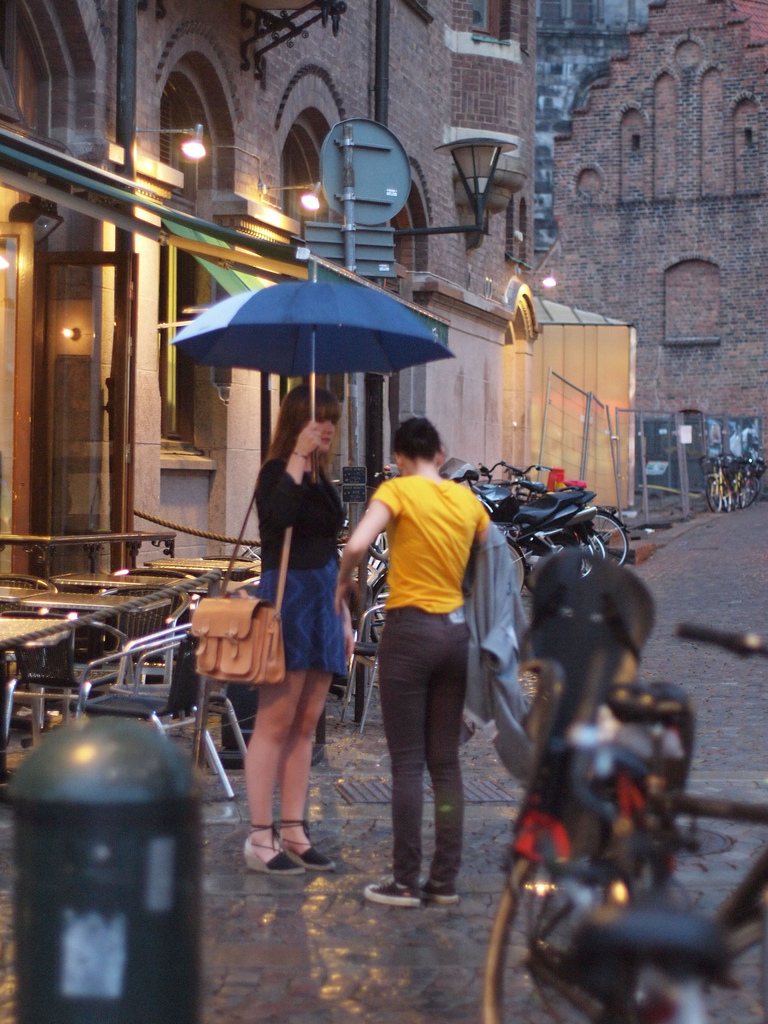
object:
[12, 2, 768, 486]
buildings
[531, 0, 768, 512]
buildings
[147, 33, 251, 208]
archways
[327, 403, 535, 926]
people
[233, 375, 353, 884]
girl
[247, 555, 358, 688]
skirt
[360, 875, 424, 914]
shoe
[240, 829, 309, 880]
shoe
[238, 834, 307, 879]
foot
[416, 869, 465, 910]
shoe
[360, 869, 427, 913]
foot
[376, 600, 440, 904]
leg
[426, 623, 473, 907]
leg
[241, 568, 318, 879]
leg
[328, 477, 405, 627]
arm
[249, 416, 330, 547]
arm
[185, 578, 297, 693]
bag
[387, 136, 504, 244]
pole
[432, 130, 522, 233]
light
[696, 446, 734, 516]
cycles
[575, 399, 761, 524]
fence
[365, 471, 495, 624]
shirt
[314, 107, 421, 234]
sign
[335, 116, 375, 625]
post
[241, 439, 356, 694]
dress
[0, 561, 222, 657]
rope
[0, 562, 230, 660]
bar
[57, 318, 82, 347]
light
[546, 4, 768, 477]
wall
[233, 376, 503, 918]
couple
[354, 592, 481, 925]
pants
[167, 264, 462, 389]
umbrella